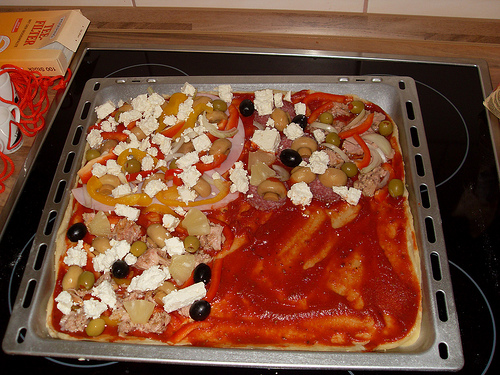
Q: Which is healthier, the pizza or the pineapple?
A: The pineapple is healthier than the pizza.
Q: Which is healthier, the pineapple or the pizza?
A: The pineapple is healthier than the pizza.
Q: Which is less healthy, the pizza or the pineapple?
A: The pizza is less healthy than the pineapple.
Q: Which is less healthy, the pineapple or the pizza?
A: The pizza is less healthy than the pineapple.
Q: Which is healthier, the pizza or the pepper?
A: The pepper is healthier than the pizza.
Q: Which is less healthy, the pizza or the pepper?
A: The pizza is less healthy than the pepper.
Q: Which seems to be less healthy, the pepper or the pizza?
A: The pizza is less healthy than the pepper.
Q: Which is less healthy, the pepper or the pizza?
A: The pizza is less healthy than the pepper.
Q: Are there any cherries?
A: No, there are no cherries.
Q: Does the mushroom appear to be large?
A: Yes, the mushroom is large.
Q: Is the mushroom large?
A: Yes, the mushroom is large.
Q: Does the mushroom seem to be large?
A: Yes, the mushroom is large.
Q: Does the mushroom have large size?
A: Yes, the mushroom is large.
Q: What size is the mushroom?
A: The mushroom is large.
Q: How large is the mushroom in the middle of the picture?
A: The mushroom is large.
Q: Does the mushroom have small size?
A: No, the mushroom is large.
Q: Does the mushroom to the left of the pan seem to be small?
A: No, the mushroom is large.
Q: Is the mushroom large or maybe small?
A: The mushroom is large.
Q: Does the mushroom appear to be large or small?
A: The mushroom is large.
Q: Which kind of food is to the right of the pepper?
A: The food is a mushroom.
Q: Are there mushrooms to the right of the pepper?
A: Yes, there is a mushroom to the right of the pepper.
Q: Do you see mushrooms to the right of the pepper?
A: Yes, there is a mushroom to the right of the pepper.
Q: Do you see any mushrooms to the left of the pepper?
A: No, the mushroom is to the right of the pepper.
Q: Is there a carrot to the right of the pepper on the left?
A: No, there is a mushroom to the right of the pepper.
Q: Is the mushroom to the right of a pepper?
A: Yes, the mushroom is to the right of a pepper.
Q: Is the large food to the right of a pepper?
A: Yes, the mushroom is to the right of a pepper.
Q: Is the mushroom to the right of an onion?
A: No, the mushroom is to the right of a pepper.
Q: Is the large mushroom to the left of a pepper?
A: No, the mushroom is to the right of a pepper.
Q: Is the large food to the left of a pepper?
A: No, the mushroom is to the right of a pepper.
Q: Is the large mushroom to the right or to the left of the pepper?
A: The mushroom is to the right of the pepper.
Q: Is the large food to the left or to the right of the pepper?
A: The mushroom is to the right of the pepper.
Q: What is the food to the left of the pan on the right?
A: The food is a mushroom.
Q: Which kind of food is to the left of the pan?
A: The food is a mushroom.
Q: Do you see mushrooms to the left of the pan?
A: Yes, there is a mushroom to the left of the pan.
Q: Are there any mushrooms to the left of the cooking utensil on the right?
A: Yes, there is a mushroom to the left of the pan.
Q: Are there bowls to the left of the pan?
A: No, there is a mushroom to the left of the pan.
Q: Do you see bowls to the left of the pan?
A: No, there is a mushroom to the left of the pan.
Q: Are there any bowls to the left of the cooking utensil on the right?
A: No, there is a mushroom to the left of the pan.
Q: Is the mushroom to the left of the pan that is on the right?
A: Yes, the mushroom is to the left of the pan.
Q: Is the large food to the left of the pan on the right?
A: Yes, the mushroom is to the left of the pan.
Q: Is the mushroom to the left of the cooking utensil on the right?
A: Yes, the mushroom is to the left of the pan.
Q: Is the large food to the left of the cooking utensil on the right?
A: Yes, the mushroom is to the left of the pan.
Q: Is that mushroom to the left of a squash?
A: No, the mushroom is to the left of the pan.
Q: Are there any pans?
A: Yes, there is a pan.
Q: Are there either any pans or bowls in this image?
A: Yes, there is a pan.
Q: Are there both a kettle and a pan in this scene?
A: No, there is a pan but no kettles.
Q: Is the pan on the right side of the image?
A: Yes, the pan is on the right of the image.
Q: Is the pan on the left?
A: No, the pan is on the right of the image.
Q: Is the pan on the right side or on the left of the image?
A: The pan is on the right of the image.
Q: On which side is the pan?
A: The pan is on the right of the image.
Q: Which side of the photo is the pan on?
A: The pan is on the right of the image.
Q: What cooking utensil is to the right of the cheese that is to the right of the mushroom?
A: The cooking utensil is a pan.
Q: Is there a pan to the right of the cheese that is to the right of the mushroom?
A: Yes, there is a pan to the right of the cheese.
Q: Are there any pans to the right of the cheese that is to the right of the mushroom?
A: Yes, there is a pan to the right of the cheese.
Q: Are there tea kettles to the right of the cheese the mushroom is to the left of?
A: No, there is a pan to the right of the cheese.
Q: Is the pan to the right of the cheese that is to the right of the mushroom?
A: Yes, the pan is to the right of the cheese.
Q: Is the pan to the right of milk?
A: No, the pan is to the right of the cheese.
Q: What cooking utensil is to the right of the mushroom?
A: The cooking utensil is a pan.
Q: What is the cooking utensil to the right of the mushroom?
A: The cooking utensil is a pan.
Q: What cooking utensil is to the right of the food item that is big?
A: The cooking utensil is a pan.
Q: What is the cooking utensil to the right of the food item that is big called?
A: The cooking utensil is a pan.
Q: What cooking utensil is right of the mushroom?
A: The cooking utensil is a pan.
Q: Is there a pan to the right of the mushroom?
A: Yes, there is a pan to the right of the mushroom.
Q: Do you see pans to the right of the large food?
A: Yes, there is a pan to the right of the mushroom.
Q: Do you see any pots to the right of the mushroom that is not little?
A: No, there is a pan to the right of the mushroom.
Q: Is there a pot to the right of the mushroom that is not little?
A: No, there is a pan to the right of the mushroom.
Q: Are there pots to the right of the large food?
A: No, there is a pan to the right of the mushroom.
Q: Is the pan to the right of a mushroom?
A: Yes, the pan is to the right of a mushroom.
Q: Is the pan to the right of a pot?
A: No, the pan is to the right of a mushroom.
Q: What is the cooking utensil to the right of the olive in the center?
A: The cooking utensil is a pan.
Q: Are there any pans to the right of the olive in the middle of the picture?
A: Yes, there is a pan to the right of the olive.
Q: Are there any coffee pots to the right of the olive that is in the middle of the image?
A: No, there is a pan to the right of the olive.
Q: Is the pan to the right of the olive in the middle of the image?
A: Yes, the pan is to the right of the olive.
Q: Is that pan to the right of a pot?
A: No, the pan is to the right of the olive.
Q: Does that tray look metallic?
A: Yes, the tray is metallic.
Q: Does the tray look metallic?
A: Yes, the tray is metallic.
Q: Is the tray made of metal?
A: Yes, the tray is made of metal.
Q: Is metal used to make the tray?
A: Yes, the tray is made of metal.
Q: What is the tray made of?
A: The tray is made of metal.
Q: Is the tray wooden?
A: No, the tray is metallic.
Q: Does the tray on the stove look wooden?
A: No, the tray is metallic.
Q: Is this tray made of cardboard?
A: No, the tray is made of metal.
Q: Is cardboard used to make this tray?
A: No, the tray is made of metal.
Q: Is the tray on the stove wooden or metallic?
A: The tray is metallic.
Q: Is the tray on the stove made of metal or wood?
A: The tray is made of metal.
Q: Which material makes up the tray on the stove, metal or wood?
A: The tray is made of metal.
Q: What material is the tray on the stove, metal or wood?
A: The tray is made of metal.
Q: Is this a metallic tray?
A: Yes, this is a metallic tray.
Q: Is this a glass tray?
A: No, this is a metallic tray.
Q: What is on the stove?
A: The tray is on the stove.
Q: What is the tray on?
A: The tray is on the stove.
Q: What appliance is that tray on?
A: The tray is on the stove.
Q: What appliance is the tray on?
A: The tray is on the stove.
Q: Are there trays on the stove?
A: Yes, there is a tray on the stove.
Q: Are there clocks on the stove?
A: No, there is a tray on the stove.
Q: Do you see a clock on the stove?
A: No, there is a tray on the stove.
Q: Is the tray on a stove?
A: Yes, the tray is on a stove.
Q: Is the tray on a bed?
A: No, the tray is on a stove.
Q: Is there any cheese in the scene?
A: Yes, there is cheese.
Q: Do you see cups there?
A: No, there are no cups.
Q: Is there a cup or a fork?
A: No, there are no cups or forks.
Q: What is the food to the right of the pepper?
A: The food is cheese.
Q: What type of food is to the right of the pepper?
A: The food is cheese.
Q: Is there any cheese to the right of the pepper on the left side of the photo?
A: Yes, there is cheese to the right of the pepper.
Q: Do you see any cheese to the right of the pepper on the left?
A: Yes, there is cheese to the right of the pepper.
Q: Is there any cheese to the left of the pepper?
A: No, the cheese is to the right of the pepper.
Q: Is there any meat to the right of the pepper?
A: No, there is cheese to the right of the pepper.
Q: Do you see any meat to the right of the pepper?
A: No, there is cheese to the right of the pepper.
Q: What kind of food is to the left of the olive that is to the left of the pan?
A: The food is cheese.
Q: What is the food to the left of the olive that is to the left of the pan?
A: The food is cheese.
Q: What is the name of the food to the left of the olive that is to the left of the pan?
A: The food is cheese.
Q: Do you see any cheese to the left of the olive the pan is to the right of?
A: Yes, there is cheese to the left of the olive.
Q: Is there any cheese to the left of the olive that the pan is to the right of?
A: Yes, there is cheese to the left of the olive.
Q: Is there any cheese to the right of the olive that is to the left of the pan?
A: No, the cheese is to the left of the olive.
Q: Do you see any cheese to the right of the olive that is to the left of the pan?
A: No, the cheese is to the left of the olive.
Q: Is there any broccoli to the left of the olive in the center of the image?
A: No, there is cheese to the left of the olive.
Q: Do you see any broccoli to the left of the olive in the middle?
A: No, there is cheese to the left of the olive.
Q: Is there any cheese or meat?
A: Yes, there is cheese.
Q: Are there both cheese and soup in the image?
A: No, there is cheese but no soup.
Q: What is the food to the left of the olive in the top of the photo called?
A: The food is cheese.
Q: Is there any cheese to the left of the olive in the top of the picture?
A: Yes, there is cheese to the left of the olive.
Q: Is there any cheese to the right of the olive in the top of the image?
A: No, the cheese is to the left of the olive.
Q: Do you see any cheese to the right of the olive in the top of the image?
A: No, the cheese is to the left of the olive.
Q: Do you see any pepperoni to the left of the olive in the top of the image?
A: No, there is cheese to the left of the olive.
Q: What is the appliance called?
A: The appliance is a stove.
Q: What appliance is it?
A: The appliance is a stove.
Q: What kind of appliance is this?
A: This is a stove.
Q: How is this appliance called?
A: This is a stove.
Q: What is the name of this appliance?
A: This is a stove.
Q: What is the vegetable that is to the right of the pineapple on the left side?
A: The vegetable is an olive.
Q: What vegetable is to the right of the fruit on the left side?
A: The vegetable is an olive.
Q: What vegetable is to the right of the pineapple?
A: The vegetable is an olive.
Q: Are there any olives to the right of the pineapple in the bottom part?
A: Yes, there is an olive to the right of the pineapple.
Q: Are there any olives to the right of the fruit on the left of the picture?
A: Yes, there is an olive to the right of the pineapple.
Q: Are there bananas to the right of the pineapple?
A: No, there is an olive to the right of the pineapple.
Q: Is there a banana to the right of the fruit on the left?
A: No, there is an olive to the right of the pineapple.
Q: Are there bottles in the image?
A: No, there are no bottles.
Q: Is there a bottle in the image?
A: No, there are no bottles.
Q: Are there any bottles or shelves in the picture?
A: No, there are no bottles or shelves.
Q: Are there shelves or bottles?
A: No, there are no bottles or shelves.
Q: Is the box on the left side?
A: Yes, the box is on the left of the image.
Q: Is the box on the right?
A: No, the box is on the left of the image.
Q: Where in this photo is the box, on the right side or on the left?
A: The box is on the left of the image.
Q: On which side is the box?
A: The box is on the left of the image.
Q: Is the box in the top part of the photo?
A: Yes, the box is in the top of the image.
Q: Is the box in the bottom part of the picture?
A: No, the box is in the top of the image.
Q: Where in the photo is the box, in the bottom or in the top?
A: The box is in the top of the image.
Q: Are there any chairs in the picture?
A: No, there are no chairs.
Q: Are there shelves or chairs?
A: No, there are no chairs or shelves.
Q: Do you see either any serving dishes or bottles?
A: No, there are no bottles or serving dishes.